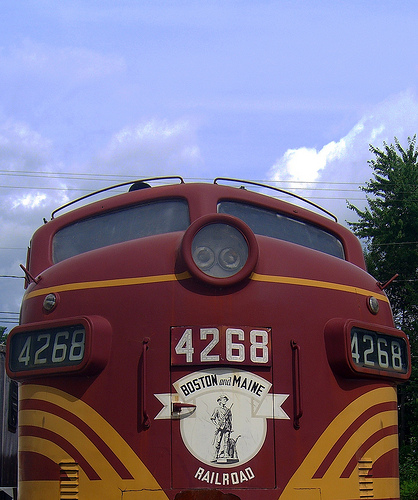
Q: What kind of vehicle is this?
A: Train.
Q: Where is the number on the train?
A: Front of the train.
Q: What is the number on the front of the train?
A: 4268.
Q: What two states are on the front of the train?
A: Boston and maine.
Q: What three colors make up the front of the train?
A: Red, yellow and white.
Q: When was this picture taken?
A: Daytime.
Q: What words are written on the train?
A: Boston and Maine Railroad.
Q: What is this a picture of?
A: Train.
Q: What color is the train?
A: Red and orange.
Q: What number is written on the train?
A: 4268.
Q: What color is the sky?
A: Blue.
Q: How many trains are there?
A: One.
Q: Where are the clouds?
A: The sky.